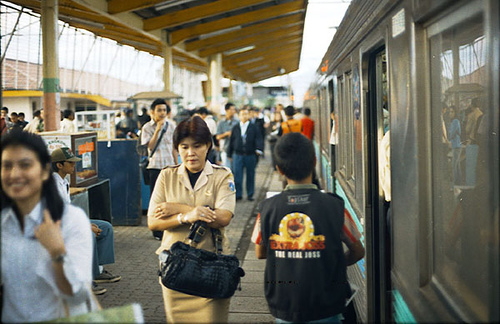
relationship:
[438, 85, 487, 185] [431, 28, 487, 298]
reflections in window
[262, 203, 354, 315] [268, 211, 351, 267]
vest has logo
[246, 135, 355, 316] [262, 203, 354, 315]
boy wearing vest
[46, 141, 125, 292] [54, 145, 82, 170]
perso wearing hat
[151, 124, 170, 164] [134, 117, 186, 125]
handbag over shoulder